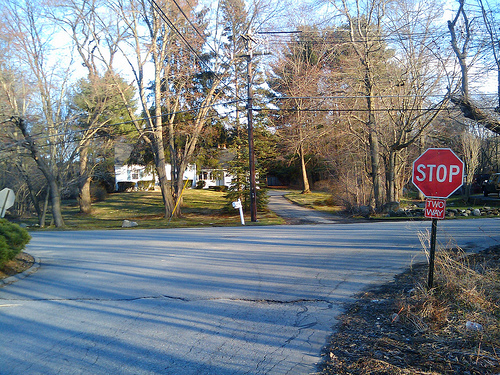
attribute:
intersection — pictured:
[7, 214, 499, 373]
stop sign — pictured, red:
[412, 146, 463, 197]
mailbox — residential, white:
[230, 198, 245, 225]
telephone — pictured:
[242, 30, 257, 222]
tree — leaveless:
[6, 1, 117, 230]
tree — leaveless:
[71, 2, 225, 221]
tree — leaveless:
[271, 21, 338, 196]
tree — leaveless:
[328, 3, 442, 215]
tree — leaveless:
[381, 6, 455, 207]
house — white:
[112, 135, 266, 195]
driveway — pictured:
[258, 183, 349, 221]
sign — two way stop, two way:
[425, 197, 446, 220]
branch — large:
[445, 8, 499, 132]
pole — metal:
[423, 213, 440, 285]